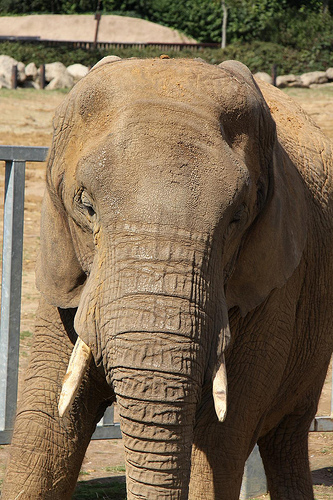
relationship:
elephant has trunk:
[0, 55, 331, 498] [82, 222, 231, 495]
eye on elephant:
[76, 192, 100, 221] [0, 55, 331, 498]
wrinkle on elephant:
[112, 389, 202, 410] [54, 53, 285, 467]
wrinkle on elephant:
[112, 389, 202, 410] [0, 55, 331, 498]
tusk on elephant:
[213, 349, 228, 424] [0, 55, 331, 498]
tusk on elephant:
[56, 337, 91, 417] [0, 55, 331, 498]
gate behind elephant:
[4, 129, 60, 375] [51, 61, 296, 410]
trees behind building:
[216, 11, 239, 44] [27, 13, 198, 48]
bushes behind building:
[241, 40, 300, 69] [27, 13, 198, 48]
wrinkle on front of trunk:
[112, 389, 202, 410] [113, 254, 200, 496]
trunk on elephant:
[113, 254, 200, 496] [0, 55, 331, 498]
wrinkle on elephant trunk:
[112, 389, 202, 410] [102, 368, 221, 493]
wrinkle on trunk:
[112, 389, 202, 410] [101, 227, 207, 498]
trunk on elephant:
[101, 227, 207, 498] [0, 55, 331, 498]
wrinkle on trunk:
[112, 389, 202, 410] [113, 254, 200, 496]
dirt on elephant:
[1, 83, 330, 498] [0, 55, 331, 498]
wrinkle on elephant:
[112, 389, 202, 410] [36, 65, 323, 498]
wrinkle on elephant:
[12, 408, 88, 456] [0, 55, 331, 498]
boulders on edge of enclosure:
[14, 41, 97, 110] [0, 86, 331, 497]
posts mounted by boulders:
[38, 63, 45, 89] [0, 53, 27, 87]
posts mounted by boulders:
[11, 62, 18, 89] [24, 61, 39, 78]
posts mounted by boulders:
[38, 63, 45, 89] [46, 73, 75, 89]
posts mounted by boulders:
[38, 63, 45, 89] [36, 59, 73, 81]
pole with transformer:
[92, 19, 100, 54] [95, 10, 102, 20]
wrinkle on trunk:
[112, 389, 202, 410] [75, 237, 231, 498]